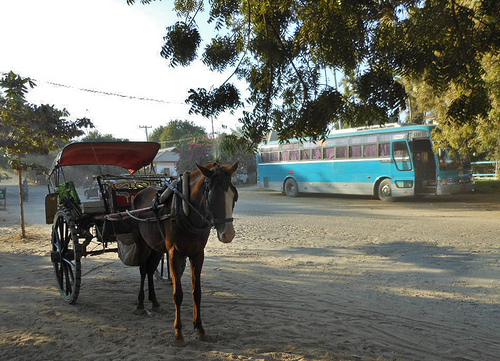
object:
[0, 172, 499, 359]
road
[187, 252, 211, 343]
legs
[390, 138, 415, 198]
door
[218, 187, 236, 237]
white fur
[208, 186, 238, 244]
face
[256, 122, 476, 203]
bus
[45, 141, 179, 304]
cart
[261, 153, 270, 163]
windows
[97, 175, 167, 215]
seat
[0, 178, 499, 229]
shadow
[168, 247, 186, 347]
horse legs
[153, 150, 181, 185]
building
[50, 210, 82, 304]
wheel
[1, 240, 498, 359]
shadow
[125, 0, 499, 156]
tree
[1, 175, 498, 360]
ground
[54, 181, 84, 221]
backpack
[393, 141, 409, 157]
window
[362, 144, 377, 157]
window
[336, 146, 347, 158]
window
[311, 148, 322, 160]
window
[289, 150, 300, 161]
window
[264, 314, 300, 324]
foot prints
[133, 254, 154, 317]
legs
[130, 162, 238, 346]
horse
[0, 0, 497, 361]
rural area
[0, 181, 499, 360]
sand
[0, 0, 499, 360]
photo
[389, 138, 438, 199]
open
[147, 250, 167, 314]
legs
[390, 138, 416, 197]
boarding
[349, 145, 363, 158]
side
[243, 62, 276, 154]
branches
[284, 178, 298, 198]
wheel